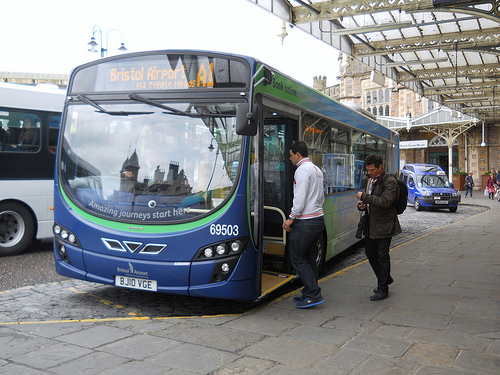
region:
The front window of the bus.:
[65, 101, 244, 223]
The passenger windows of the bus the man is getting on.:
[306, 119, 391, 194]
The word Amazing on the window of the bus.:
[83, 194, 118, 216]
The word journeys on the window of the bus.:
[117, 206, 150, 220]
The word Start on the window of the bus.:
[151, 211, 171, 218]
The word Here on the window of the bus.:
[170, 207, 193, 219]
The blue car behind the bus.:
[402, 169, 460, 214]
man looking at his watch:
[353, 152, 408, 305]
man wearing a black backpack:
[350, 150, 410, 305]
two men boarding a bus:
[52, 48, 408, 311]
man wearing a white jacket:
[281, 136, 327, 310]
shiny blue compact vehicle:
[400, 162, 465, 213]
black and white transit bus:
[1, 83, 66, 258]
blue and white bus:
[51, 48, 401, 304]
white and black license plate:
[112, 275, 159, 292]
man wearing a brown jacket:
[354, 151, 408, 302]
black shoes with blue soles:
[292, 288, 324, 310]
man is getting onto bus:
[278, 135, 327, 316]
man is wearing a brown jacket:
[355, 154, 406, 308]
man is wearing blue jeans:
[284, 210, 327, 317]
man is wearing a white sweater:
[285, 157, 324, 223]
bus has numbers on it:
[204, 218, 243, 238]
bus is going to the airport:
[100, 55, 196, 90]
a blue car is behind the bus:
[400, 155, 461, 215]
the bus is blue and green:
[54, 52, 402, 310]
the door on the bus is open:
[258, 90, 302, 297]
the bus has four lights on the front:
[194, 235, 245, 287]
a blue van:
[395, 159, 462, 213]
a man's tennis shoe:
[292, 292, 325, 314]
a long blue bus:
[55, 52, 411, 311]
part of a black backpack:
[387, 171, 412, 217]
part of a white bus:
[0, 79, 68, 256]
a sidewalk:
[0, 214, 497, 372]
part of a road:
[0, 248, 75, 286]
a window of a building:
[361, 90, 372, 106]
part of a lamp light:
[86, 21, 133, 56]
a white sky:
[122, 0, 334, 78]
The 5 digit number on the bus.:
[208, 220, 241, 237]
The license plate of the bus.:
[112, 275, 157, 290]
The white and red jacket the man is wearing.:
[288, 157, 325, 217]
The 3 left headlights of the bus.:
[52, 223, 77, 239]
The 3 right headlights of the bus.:
[200, 242, 238, 259]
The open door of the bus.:
[262, 119, 301, 285]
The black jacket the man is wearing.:
[359, 172, 401, 244]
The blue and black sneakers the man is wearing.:
[295, 294, 323, 308]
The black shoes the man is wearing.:
[370, 281, 393, 303]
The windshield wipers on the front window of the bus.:
[75, 89, 237, 119]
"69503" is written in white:
[205, 217, 241, 237]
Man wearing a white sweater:
[284, 139, 330, 221]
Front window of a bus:
[59, 94, 251, 234]